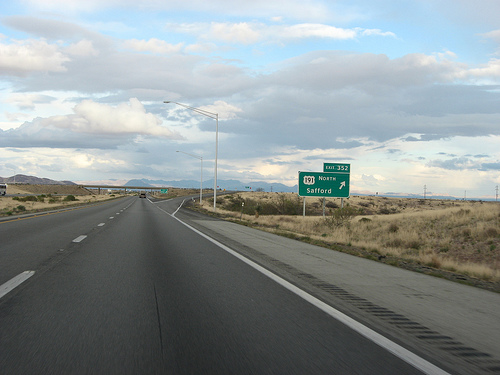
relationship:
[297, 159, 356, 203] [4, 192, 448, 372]
sign on road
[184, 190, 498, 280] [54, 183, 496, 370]
brown grass on highway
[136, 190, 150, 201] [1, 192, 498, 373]
car on highway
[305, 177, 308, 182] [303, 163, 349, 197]
black number on sign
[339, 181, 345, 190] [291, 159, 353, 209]
arrow on sign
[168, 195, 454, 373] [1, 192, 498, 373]
line drawn highway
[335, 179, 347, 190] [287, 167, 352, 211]
arrow pointing sign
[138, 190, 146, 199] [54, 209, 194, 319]
car driving highway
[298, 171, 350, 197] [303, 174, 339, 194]
green sign has lettering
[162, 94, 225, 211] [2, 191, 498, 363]
lamp beside road